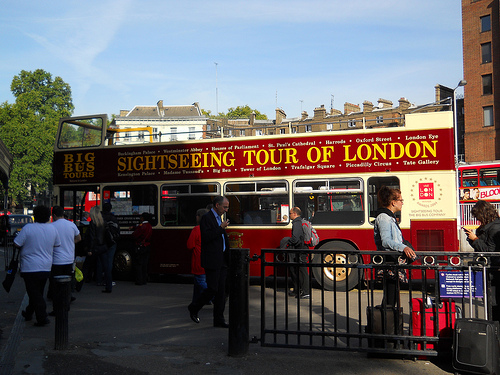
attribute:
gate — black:
[253, 242, 498, 365]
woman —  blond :
[82, 204, 125, 291]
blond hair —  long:
[86, 207, 107, 232]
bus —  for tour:
[67, 123, 495, 288]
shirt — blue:
[212, 210, 227, 250]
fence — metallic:
[309, 265, 387, 342]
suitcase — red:
[409, 263, 456, 358]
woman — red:
[372, 183, 409, 346]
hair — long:
[377, 182, 402, 207]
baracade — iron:
[254, 243, 499, 365]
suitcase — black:
[446, 256, 498, 373]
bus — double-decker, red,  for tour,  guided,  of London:
[48, 113, 460, 291]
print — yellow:
[62, 147, 97, 177]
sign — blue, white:
[441, 270, 490, 298]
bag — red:
[413, 299, 454, 351]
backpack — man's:
[299, 219, 326, 254]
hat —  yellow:
[70, 262, 85, 291]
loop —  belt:
[56, 265, 78, 270]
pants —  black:
[292, 242, 312, 292]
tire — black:
[304, 234, 368, 296]